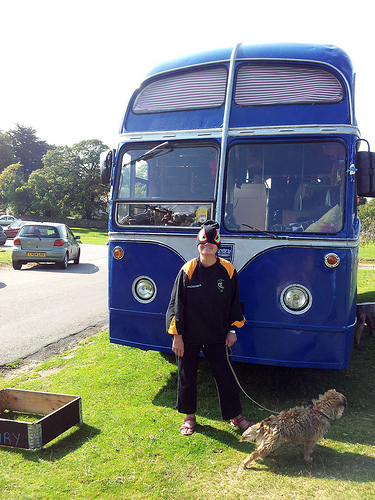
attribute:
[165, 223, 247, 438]
person — posing, standing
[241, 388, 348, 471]
dog — brown, small, shaggy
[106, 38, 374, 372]
bus — blue, parked, white, large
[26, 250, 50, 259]
plate — yellow, black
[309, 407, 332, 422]
collar — red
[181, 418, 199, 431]
straps — red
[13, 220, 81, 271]
car — sliver, gray, rolling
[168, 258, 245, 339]
jacket — black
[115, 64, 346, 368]
front — gray, blue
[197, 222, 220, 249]
hat — black, funny, orange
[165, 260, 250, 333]
shirt — black, yellow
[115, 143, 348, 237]
windshields — big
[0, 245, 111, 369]
pavement — gray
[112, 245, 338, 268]
lights — orange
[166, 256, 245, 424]
outfit — athletic, black, yellow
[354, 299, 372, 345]
man — looking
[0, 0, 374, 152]
sky — sunny, clear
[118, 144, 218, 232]
window — open